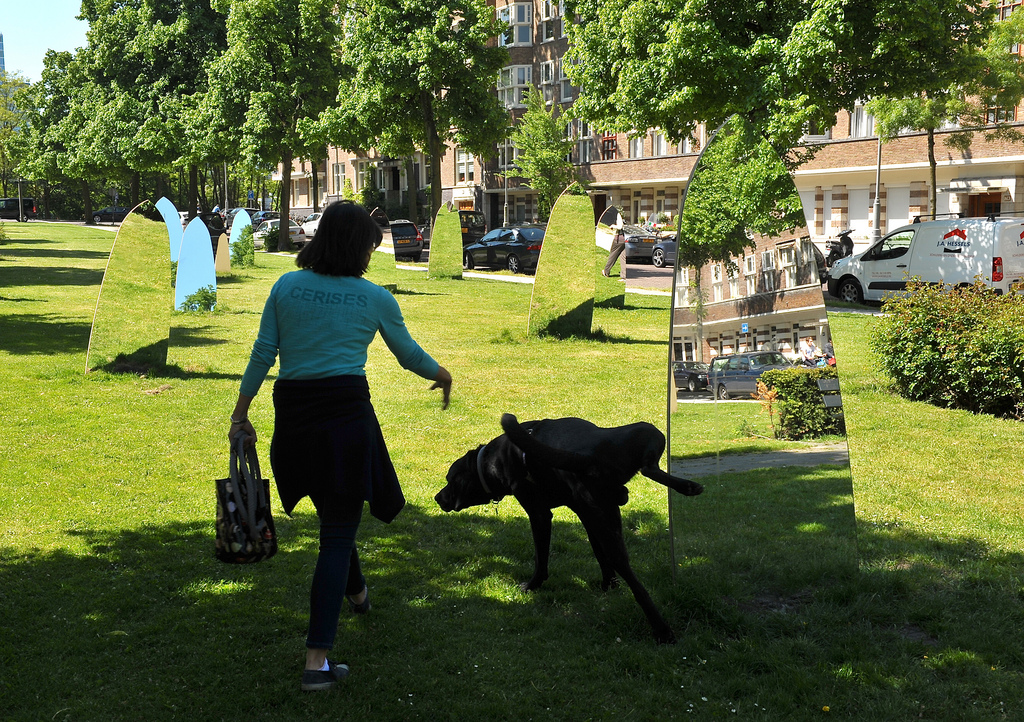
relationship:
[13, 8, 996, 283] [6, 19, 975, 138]
trees have leaves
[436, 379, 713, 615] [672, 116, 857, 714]
dog peeing on mirror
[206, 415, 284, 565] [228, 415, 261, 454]
bag in hand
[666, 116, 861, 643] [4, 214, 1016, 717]
mirror in park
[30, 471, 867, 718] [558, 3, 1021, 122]
shadow of tree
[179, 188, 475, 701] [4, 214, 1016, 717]
woman walking in park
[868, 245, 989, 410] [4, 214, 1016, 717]
bush in park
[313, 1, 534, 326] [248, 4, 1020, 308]
tree near curb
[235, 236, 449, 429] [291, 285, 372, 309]
shirt has writing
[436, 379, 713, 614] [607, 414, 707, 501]
dog lifting leg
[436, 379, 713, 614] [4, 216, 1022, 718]
dog walking in grass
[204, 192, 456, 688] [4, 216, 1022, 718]
woman walking in grass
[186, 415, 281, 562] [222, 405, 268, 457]
bag in hand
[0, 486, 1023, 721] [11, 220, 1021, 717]
shadow on ground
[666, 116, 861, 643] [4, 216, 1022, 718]
mirror standing on grass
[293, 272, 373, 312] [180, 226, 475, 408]
writing on shirt